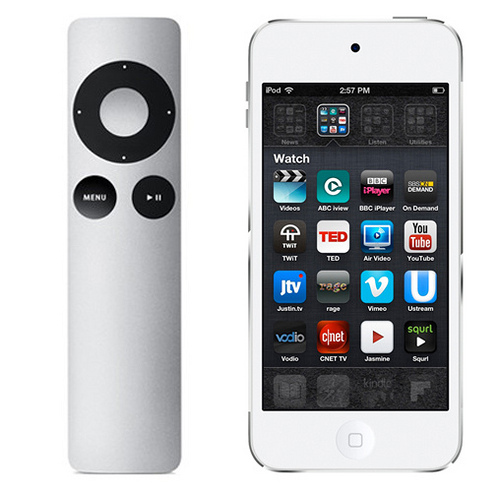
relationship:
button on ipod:
[318, 321, 348, 360] [249, 15, 466, 471]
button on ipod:
[360, 319, 395, 359] [249, 15, 466, 471]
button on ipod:
[405, 271, 439, 308] [249, 15, 466, 471]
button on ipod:
[273, 270, 307, 307] [249, 15, 466, 471]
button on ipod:
[273, 158, 314, 208] [249, 15, 466, 471]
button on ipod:
[362, 166, 395, 207] [249, 15, 466, 471]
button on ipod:
[315, 169, 355, 202] [249, 15, 466, 471]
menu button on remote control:
[70, 174, 117, 217] [64, 17, 184, 476]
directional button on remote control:
[72, 59, 176, 166] [64, 17, 184, 476]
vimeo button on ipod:
[361, 269, 395, 314] [249, 15, 466, 471]